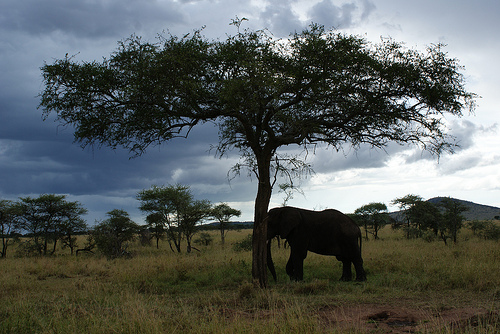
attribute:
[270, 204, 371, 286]
elephant — gray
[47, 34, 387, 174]
tree — big, wide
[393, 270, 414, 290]
grass — dry, yellow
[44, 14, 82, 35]
sky — gray, light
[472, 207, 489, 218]
mountain — tall